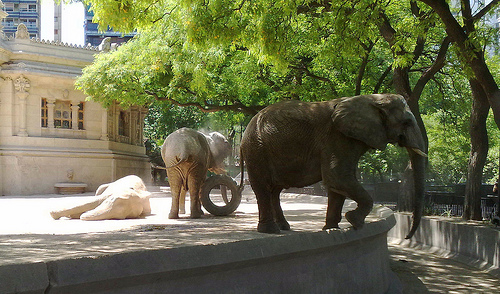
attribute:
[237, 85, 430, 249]
elephant — dark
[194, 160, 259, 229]
tire — black, rubber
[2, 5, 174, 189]
building — white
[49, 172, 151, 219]
elephant — lying down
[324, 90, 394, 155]
ear — grey, dark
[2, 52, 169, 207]
bench — distant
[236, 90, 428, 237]
elephant — large, big, grey, dark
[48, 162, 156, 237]
elephant — light colored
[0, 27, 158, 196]
building — white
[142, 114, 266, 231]
elephant — grey 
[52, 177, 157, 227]
elephant — light colored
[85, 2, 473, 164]
leaves — green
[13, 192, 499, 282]
ground — sunny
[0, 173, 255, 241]
sunlight — shining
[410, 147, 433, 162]
tusk — white